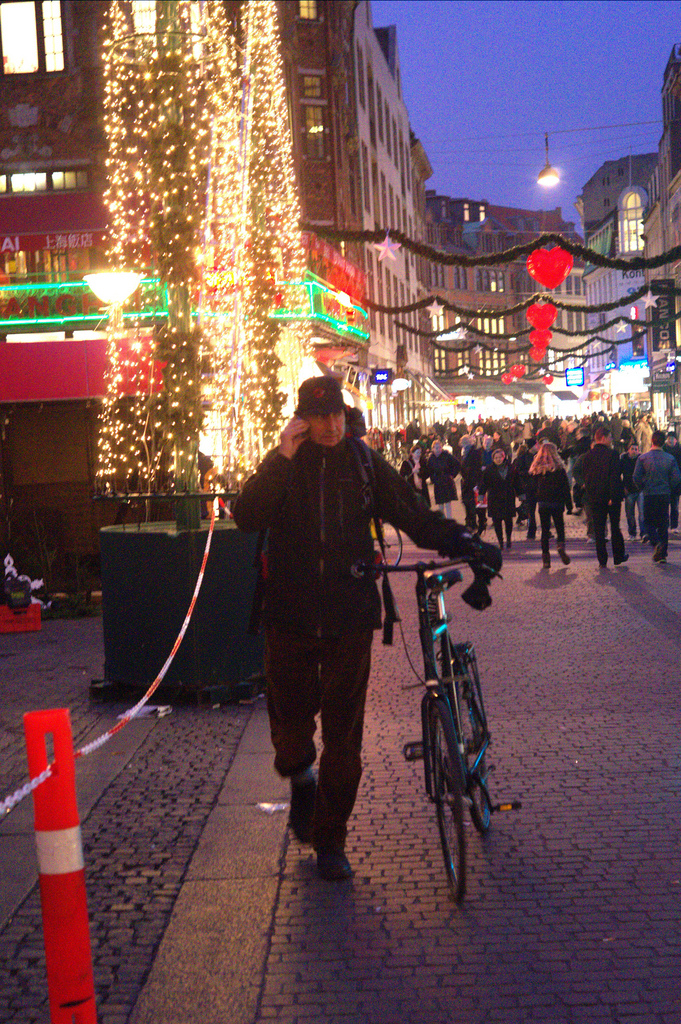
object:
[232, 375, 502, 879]
man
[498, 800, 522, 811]
pedal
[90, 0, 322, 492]
christmastree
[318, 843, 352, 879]
shoes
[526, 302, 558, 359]
red balls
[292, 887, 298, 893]
brick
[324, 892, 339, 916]
brick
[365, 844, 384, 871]
brick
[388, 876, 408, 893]
brick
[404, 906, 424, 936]
brick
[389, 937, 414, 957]
brick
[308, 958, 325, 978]
brick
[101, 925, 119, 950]
brick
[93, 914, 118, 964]
brick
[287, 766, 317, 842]
shoes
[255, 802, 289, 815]
wrapper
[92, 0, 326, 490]
lights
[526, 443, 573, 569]
person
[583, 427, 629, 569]
person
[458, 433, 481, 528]
person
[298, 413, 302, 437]
cellphone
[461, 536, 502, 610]
glove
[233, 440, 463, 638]
jacket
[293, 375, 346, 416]
hat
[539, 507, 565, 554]
jeans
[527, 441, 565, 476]
hair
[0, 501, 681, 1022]
ground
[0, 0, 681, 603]
building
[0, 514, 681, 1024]
sidewalk